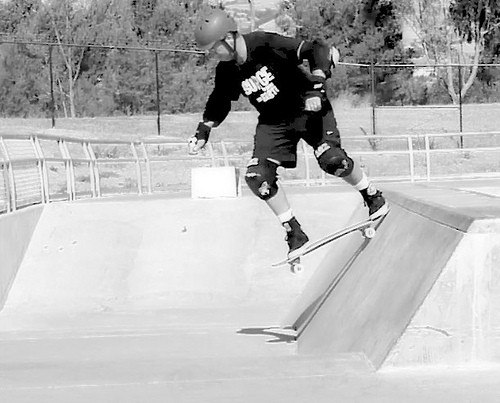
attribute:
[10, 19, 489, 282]
picture — white, black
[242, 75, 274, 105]
lettering — white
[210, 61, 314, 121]
shirt — black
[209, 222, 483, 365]
ramp — concrete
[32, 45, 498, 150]
fence — metal, chain link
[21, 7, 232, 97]
trees — lush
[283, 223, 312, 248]
shoes — white, black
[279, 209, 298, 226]
socks — white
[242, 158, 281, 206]
knee pads — black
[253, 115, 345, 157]
shorts — black